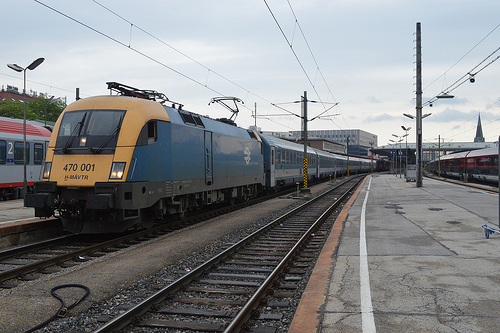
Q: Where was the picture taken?
A: It was taken at the station.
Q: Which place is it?
A: It is a station.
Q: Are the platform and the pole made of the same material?
A: No, the platform is made of cement and the pole is made of wood.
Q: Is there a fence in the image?
A: No, there are no fences.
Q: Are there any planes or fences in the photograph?
A: No, there are no fences or planes.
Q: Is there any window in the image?
A: Yes, there is a window.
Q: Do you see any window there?
A: Yes, there is a window.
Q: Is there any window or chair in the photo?
A: Yes, there is a window.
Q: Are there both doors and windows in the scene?
A: Yes, there are both a window and a door.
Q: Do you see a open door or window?
A: Yes, there is an open window.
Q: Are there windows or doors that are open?
A: Yes, the window is open.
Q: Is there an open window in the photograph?
A: Yes, there is an open window.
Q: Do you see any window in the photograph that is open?
A: Yes, there is a window that is open.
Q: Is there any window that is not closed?
A: Yes, there is a open window.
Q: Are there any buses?
A: No, there are no buses.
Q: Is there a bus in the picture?
A: No, there are no buses.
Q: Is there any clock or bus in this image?
A: No, there are no buses or clocks.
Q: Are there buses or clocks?
A: No, there are no buses or clocks.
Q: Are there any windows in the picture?
A: Yes, there are windows.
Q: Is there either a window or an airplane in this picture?
A: Yes, there are windows.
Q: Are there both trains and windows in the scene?
A: Yes, there are both windows and a train.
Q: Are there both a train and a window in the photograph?
A: Yes, there are both a window and a train.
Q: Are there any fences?
A: No, there are no fences.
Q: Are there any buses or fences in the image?
A: No, there are no fences or buses.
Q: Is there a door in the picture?
A: Yes, there is a door.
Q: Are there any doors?
A: Yes, there is a door.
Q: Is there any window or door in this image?
A: Yes, there is a door.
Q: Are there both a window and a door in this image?
A: Yes, there are both a door and a window.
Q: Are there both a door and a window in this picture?
A: Yes, there are both a door and a window.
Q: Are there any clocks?
A: No, there are no clocks.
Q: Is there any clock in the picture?
A: No, there are no clocks.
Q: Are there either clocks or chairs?
A: No, there are no clocks or chairs.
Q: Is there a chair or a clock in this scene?
A: No, there are no clocks or chairs.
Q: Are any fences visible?
A: No, there are no fences.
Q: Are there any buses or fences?
A: No, there are no fences or buses.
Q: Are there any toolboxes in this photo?
A: No, there are no toolboxes.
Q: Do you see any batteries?
A: No, there are no batteries.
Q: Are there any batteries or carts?
A: No, there are no batteries or carts.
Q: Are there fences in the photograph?
A: No, there are no fences.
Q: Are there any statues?
A: No, there are no statues.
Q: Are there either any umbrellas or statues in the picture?
A: No, there are no statues or umbrellas.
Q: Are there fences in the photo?
A: No, there are no fences.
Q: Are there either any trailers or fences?
A: No, there are no fences or trailers.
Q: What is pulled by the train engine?
A: The cars are pulled by the train engine.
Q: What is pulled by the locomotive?
A: The cars are pulled by the train engine.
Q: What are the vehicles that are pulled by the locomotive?
A: The vehicles are cars.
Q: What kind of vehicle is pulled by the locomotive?
A: The vehicles are cars.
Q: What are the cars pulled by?
A: The cars are pulled by the locomotive.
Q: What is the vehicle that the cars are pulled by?
A: The vehicle is a locomotive.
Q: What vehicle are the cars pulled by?
A: The cars are pulled by the engine.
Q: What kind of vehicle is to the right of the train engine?
A: The vehicles are cars.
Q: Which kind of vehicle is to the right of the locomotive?
A: The vehicles are cars.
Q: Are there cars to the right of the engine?
A: Yes, there are cars to the right of the engine.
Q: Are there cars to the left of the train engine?
A: No, the cars are to the right of the train engine.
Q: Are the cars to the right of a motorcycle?
A: No, the cars are to the right of a locomotive.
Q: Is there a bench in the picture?
A: No, there are no benches.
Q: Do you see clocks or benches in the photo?
A: No, there are no benches or clocks.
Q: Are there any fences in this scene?
A: No, there are no fences.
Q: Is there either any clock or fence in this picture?
A: No, there are no fences or clocks.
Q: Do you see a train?
A: Yes, there is a train.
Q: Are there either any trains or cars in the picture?
A: Yes, there is a train.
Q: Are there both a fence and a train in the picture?
A: No, there is a train but no fences.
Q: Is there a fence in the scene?
A: No, there are no fences.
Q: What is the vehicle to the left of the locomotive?
A: The vehicle is a train.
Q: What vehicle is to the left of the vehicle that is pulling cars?
A: The vehicle is a train.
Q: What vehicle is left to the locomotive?
A: The vehicle is a train.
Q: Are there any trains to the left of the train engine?
A: Yes, there is a train to the left of the train engine.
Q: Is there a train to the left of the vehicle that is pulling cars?
A: Yes, there is a train to the left of the train engine.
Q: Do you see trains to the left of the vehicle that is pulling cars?
A: Yes, there is a train to the left of the train engine.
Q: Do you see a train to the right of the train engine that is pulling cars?
A: No, the train is to the left of the engine.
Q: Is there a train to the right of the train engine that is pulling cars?
A: No, the train is to the left of the engine.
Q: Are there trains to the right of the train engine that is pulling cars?
A: No, the train is to the left of the engine.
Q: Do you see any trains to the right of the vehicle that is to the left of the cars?
A: No, the train is to the left of the engine.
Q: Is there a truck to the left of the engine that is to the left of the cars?
A: No, there is a train to the left of the engine.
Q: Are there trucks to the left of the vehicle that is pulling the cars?
A: No, there is a train to the left of the engine.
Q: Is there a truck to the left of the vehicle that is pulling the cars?
A: No, there is a train to the left of the engine.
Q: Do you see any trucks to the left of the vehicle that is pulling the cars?
A: No, there is a train to the left of the engine.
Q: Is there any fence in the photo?
A: No, there are no fences.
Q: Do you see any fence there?
A: No, there are no fences.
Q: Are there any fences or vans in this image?
A: No, there are no fences or vans.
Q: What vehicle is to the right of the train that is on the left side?
A: The vehicle is a locomotive.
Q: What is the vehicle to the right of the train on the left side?
A: The vehicle is a locomotive.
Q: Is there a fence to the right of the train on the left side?
A: No, there is a locomotive to the right of the train.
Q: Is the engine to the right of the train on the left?
A: Yes, the engine is to the right of the train.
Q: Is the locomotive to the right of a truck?
A: No, the locomotive is to the right of the train.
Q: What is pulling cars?
A: The train engine is pulling cars.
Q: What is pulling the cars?
A: The train engine is pulling cars.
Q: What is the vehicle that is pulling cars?
A: The vehicle is a locomotive.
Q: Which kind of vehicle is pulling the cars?
A: The vehicle is a locomotive.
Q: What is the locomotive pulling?
A: The locomotive is pulling cars.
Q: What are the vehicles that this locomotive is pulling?
A: The vehicles are cars.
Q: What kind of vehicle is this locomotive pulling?
A: The locomotive is pulling cars.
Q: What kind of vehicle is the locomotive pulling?
A: The locomotive is pulling cars.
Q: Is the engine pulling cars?
A: Yes, the engine is pulling cars.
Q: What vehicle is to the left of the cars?
A: The vehicle is a locomotive.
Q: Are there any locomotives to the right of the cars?
A: No, the locomotive is to the left of the cars.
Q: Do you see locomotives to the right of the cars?
A: No, the locomotive is to the left of the cars.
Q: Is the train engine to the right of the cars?
A: No, the train engine is to the left of the cars.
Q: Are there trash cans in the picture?
A: No, there are no trash cans.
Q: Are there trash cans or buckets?
A: No, there are no trash cans or buckets.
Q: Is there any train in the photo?
A: Yes, there is a train.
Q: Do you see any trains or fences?
A: Yes, there is a train.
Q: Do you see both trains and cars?
A: Yes, there are both a train and a car.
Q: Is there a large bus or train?
A: Yes, there is a large train.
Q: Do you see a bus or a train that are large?
A: Yes, the train is large.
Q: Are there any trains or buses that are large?
A: Yes, the train is large.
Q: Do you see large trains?
A: Yes, there is a large train.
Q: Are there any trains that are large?
A: Yes, there is a train that is large.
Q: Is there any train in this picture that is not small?
A: Yes, there is a large train.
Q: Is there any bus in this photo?
A: No, there are no buses.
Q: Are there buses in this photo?
A: No, there are no buses.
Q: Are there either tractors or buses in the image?
A: No, there are no buses or tractors.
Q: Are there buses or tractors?
A: No, there are no buses or tractors.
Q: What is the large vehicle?
A: The vehicle is a train.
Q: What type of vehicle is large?
A: The vehicle is a train.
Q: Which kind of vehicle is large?
A: The vehicle is a train.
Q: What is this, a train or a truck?
A: This is a train.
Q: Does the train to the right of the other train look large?
A: Yes, the train is large.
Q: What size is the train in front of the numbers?
A: The train is large.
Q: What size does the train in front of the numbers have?
A: The train has large size.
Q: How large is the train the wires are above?
A: The train is large.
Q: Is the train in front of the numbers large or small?
A: The train is large.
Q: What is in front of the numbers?
A: The train is in front of the numbers.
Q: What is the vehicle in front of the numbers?
A: The vehicle is a train.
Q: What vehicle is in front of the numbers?
A: The vehicle is a train.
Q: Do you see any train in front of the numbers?
A: Yes, there is a train in front of the numbers.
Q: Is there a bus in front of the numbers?
A: No, there is a train in front of the numbers.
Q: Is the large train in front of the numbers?
A: Yes, the train is in front of the numbers.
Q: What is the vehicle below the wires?
A: The vehicle is a train.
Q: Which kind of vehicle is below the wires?
A: The vehicle is a train.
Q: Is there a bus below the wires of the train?
A: No, there is a train below the wires.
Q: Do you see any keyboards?
A: No, there are no keyboards.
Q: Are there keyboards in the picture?
A: No, there are no keyboards.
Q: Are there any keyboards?
A: No, there are no keyboards.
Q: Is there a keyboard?
A: No, there are no keyboards.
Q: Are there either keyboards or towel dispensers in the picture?
A: No, there are no keyboards or towel dispensers.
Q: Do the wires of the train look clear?
A: Yes, the wires are clear.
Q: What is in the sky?
A: The wires are in the sky.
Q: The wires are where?
A: The wires are in the sky.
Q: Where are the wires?
A: The wires are in the sky.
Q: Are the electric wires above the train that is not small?
A: Yes, the wires are above the train.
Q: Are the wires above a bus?
A: No, the wires are above the train.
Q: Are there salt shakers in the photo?
A: No, there are no salt shakers.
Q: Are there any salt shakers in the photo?
A: No, there are no salt shakers.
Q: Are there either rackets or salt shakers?
A: No, there are no salt shakers or rackets.